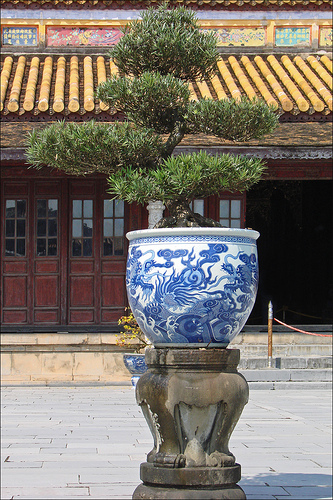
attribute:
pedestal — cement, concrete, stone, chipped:
[132, 346, 252, 499]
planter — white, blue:
[117, 220, 263, 351]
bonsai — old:
[20, 2, 291, 227]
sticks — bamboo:
[2, 46, 332, 116]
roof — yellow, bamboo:
[3, 3, 332, 172]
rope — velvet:
[276, 315, 333, 344]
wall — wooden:
[1, 162, 131, 337]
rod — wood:
[52, 52, 69, 113]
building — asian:
[2, 5, 331, 334]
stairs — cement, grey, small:
[237, 324, 332, 386]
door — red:
[3, 162, 73, 336]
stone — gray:
[247, 321, 333, 349]